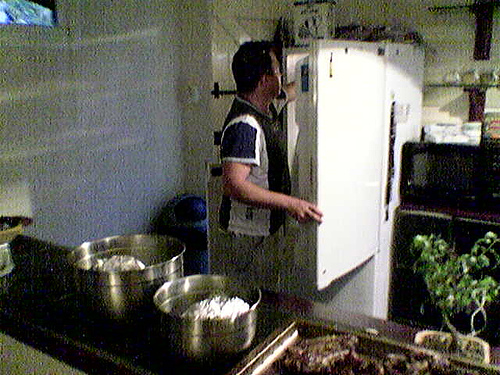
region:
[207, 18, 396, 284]
a man looking in a refrigerator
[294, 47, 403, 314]
a white refrigerator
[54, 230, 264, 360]
two large silver pots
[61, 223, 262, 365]
two large silver pots full of rice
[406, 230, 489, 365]
a small Bonsai tree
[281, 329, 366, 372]
a large steak on a stove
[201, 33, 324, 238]
an Asian man with a blue and white shirt on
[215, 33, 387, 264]
a man holding a refrigerator door open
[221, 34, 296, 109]
a man with black hair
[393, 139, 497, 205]
a black microwave oven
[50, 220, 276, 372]
two stainless steel pots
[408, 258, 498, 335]
plant in the kitchen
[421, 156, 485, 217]
microwave on the counter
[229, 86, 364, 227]
man has the refrigerator door open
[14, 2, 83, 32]
window in the kitchen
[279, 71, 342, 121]
man has his arm in the refrigerator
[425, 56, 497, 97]
shelf above the microwave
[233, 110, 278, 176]
man is wearing a blue and white shirt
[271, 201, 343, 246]
man has his hand on the refrigerator door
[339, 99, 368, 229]
refrigerator is white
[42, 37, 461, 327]
This photo is blurry.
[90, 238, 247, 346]
There is food in the pots.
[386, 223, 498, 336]
This tree is small.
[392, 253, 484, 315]
The leaves are green.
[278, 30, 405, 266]
This is a fridge.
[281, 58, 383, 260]
The fridge is white in color.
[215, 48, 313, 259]
The man is cooking.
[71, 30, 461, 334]
this is in a kitchen.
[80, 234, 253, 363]
The pots are silver.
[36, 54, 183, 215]
The wall is white in color.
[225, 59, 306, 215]
this is a man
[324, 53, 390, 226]
this is a refrigerator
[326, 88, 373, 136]
the refrigerator is white in color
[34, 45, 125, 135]
this is the wall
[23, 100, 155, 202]
the wall is white in color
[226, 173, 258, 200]
the man is light skinned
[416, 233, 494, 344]
this is a tree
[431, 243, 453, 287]
the leaves are green in color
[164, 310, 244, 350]
this is a sufuria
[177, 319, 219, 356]
the container is metallic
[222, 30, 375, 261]
A man reaching into the fridge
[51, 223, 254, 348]
pots cooking on the stove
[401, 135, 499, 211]
a black microwave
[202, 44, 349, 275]
a man reaching for food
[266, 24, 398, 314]
an open refrigerator door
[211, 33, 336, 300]
a man cooking in his kitchen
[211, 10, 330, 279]
a man preparing a meal in the kitchen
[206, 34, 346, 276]
a man making dinner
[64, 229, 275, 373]
silver pots with noodles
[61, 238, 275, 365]
silver pots on the stove